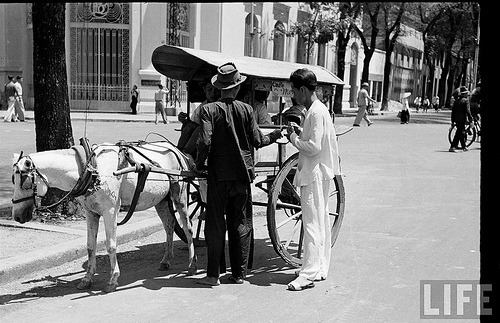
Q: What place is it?
A: It is a street.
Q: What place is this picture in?
A: It is at the street.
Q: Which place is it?
A: It is a street.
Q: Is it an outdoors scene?
A: Yes, it is outdoors.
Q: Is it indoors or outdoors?
A: It is outdoors.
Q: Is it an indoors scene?
A: No, it is outdoors.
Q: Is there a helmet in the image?
A: No, there are no helmets.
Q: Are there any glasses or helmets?
A: No, there are no helmets or glasses.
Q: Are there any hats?
A: Yes, there is a hat.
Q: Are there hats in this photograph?
A: Yes, there is a hat.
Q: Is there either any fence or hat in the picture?
A: Yes, there is a hat.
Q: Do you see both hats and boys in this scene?
A: No, there is a hat but no boys.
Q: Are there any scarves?
A: No, there are no scarves.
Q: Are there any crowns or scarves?
A: No, there are no scarves or crowns.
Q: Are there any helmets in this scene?
A: No, there are no helmets.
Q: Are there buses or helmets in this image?
A: No, there are no helmets or buses.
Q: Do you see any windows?
A: Yes, there is a window.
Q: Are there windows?
A: Yes, there is a window.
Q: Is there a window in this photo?
A: Yes, there is a window.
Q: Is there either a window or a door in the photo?
A: Yes, there is a window.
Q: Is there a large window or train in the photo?
A: Yes, there is a large window.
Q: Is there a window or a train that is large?
A: Yes, the window is large.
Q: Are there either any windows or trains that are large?
A: Yes, the window is large.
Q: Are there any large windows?
A: Yes, there is a large window.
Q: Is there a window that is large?
A: Yes, there is a window that is large.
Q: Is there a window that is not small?
A: Yes, there is a large window.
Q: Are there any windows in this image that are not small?
A: Yes, there is a large window.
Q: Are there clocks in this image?
A: No, there are no clocks.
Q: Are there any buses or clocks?
A: No, there are no clocks or buses.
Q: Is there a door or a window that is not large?
A: No, there is a window but it is large.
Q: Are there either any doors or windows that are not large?
A: No, there is a window but it is large.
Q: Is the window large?
A: Yes, the window is large.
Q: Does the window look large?
A: Yes, the window is large.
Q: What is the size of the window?
A: The window is large.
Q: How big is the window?
A: The window is large.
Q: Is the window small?
A: No, the window is large.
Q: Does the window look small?
A: No, the window is large.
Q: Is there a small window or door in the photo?
A: No, there is a window but it is large.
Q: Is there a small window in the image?
A: No, there is a window but it is large.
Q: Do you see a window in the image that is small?
A: No, there is a window but it is large.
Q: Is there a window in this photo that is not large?
A: No, there is a window but it is large.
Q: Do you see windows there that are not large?
A: No, there is a window but it is large.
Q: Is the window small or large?
A: The window is large.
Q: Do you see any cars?
A: No, there are no cars.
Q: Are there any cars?
A: No, there are no cars.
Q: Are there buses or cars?
A: No, there are no cars or buses.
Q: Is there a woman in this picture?
A: No, there are no women.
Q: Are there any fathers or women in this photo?
A: No, there are no women or fathers.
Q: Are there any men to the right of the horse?
A: Yes, there is a man to the right of the horse.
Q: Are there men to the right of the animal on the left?
A: Yes, there is a man to the right of the horse.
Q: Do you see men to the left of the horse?
A: No, the man is to the right of the horse.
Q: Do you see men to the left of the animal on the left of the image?
A: No, the man is to the right of the horse.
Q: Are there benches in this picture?
A: No, there are no benches.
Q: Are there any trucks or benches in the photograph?
A: No, there are no benches or trucks.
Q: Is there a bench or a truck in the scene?
A: No, there are no benches or trucks.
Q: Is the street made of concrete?
A: Yes, the street is made of concrete.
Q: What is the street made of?
A: The street is made of concrete.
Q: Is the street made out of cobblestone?
A: No, the street is made of concrete.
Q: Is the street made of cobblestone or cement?
A: The street is made of cement.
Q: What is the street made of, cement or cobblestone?
A: The street is made of cement.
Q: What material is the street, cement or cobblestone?
A: The street is made of cement.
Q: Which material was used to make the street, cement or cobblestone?
A: The street is made of cement.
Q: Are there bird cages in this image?
A: No, there are no bird cages.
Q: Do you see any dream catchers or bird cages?
A: No, there are no bird cages or dream catchers.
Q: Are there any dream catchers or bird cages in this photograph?
A: No, there are no bird cages or dream catchers.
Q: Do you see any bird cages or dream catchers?
A: No, there are no bird cages or dream catchers.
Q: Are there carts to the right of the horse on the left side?
A: Yes, there is a cart to the right of the horse.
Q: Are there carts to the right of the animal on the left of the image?
A: Yes, there is a cart to the right of the horse.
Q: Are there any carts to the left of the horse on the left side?
A: No, the cart is to the right of the horse.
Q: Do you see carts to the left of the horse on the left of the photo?
A: No, the cart is to the right of the horse.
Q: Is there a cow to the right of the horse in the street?
A: No, there is a cart to the right of the horse.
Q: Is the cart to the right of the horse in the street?
A: Yes, the cart is to the right of the horse.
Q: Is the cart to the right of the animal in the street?
A: Yes, the cart is to the right of the horse.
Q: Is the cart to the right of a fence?
A: No, the cart is to the right of the horse.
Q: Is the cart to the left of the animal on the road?
A: No, the cart is to the right of the horse.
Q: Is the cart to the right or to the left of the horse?
A: The cart is to the right of the horse.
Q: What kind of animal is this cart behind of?
A: The cart is behind the horse.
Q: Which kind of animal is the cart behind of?
A: The cart is behind the horse.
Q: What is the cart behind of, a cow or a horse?
A: The cart is behind a horse.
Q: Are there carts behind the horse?
A: Yes, there is a cart behind the horse.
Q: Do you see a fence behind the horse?
A: No, there is a cart behind the horse.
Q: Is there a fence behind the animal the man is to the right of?
A: No, there is a cart behind the horse.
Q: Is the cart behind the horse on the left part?
A: Yes, the cart is behind the horse.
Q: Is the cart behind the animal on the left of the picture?
A: Yes, the cart is behind the horse.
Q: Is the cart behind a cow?
A: No, the cart is behind the horse.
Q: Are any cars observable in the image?
A: No, there are no cars.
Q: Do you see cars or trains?
A: No, there are no cars or trains.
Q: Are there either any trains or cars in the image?
A: No, there are no cars or trains.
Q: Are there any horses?
A: Yes, there is a horse.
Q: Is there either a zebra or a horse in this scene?
A: Yes, there is a horse.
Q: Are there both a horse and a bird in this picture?
A: No, there is a horse but no birds.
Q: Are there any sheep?
A: No, there are no sheep.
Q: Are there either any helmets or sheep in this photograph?
A: No, there are no sheep or helmets.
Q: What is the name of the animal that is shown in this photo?
A: The animal is a horse.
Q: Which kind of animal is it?
A: The animal is a horse.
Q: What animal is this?
A: That is a horse.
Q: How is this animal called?
A: That is a horse.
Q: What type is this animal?
A: That is a horse.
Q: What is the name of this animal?
A: That is a horse.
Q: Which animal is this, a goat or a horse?
A: That is a horse.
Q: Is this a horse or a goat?
A: This is a horse.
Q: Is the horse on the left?
A: Yes, the horse is on the left of the image.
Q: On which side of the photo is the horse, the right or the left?
A: The horse is on the left of the image.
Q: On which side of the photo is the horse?
A: The horse is on the left of the image.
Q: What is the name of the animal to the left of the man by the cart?
A: The animal is a horse.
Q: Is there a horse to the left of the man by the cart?
A: Yes, there is a horse to the left of the man.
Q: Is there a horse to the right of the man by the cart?
A: No, the horse is to the left of the man.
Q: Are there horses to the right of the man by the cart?
A: No, the horse is to the left of the man.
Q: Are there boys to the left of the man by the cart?
A: No, there is a horse to the left of the man.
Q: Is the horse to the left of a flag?
A: No, the horse is to the left of a man.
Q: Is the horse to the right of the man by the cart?
A: No, the horse is to the left of the man.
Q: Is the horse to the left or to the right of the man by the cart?
A: The horse is to the left of the man.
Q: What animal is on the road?
A: The horse is on the road.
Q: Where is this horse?
A: The horse is on the road.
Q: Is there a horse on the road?
A: Yes, there is a horse on the road.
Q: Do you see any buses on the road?
A: No, there is a horse on the road.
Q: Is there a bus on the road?
A: No, there is a horse on the road.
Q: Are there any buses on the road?
A: No, there is a horse on the road.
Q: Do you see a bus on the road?
A: No, there is a horse on the road.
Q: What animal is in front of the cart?
A: The horse is in front of the cart.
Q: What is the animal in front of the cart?
A: The animal is a horse.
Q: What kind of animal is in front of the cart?
A: The animal is a horse.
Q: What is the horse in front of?
A: The horse is in front of the cart.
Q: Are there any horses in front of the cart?
A: Yes, there is a horse in front of the cart.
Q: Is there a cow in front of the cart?
A: No, there is a horse in front of the cart.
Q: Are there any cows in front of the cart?
A: No, there is a horse in front of the cart.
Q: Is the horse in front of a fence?
A: No, the horse is in front of the cart.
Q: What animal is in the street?
A: The horse is in the street.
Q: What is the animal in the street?
A: The animal is a horse.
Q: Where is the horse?
A: The horse is in the street.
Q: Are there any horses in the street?
A: Yes, there is a horse in the street.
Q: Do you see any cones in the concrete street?
A: No, there is a horse in the street.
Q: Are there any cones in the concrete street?
A: No, there is a horse in the street.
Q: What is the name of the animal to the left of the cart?
A: The animal is a horse.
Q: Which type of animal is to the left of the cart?
A: The animal is a horse.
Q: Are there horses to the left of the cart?
A: Yes, there is a horse to the left of the cart.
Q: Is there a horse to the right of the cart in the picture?
A: No, the horse is to the left of the cart.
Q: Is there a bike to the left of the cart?
A: No, there is a horse to the left of the cart.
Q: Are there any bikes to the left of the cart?
A: No, there is a horse to the left of the cart.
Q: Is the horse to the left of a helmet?
A: No, the horse is to the left of the cart.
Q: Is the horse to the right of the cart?
A: No, the horse is to the left of the cart.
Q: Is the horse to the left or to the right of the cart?
A: The horse is to the left of the cart.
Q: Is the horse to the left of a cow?
A: No, the horse is to the left of a man.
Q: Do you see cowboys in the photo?
A: No, there are no cowboys.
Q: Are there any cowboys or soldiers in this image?
A: No, there are no cowboys or soldiers.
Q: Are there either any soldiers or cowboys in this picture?
A: No, there are no cowboys or soldiers.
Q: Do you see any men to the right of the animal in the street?
A: Yes, there is a man to the right of the horse.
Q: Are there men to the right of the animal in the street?
A: Yes, there is a man to the right of the horse.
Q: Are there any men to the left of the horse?
A: No, the man is to the right of the horse.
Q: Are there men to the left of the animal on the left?
A: No, the man is to the right of the horse.